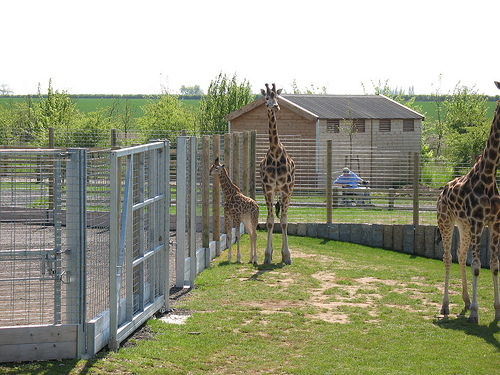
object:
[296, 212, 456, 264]
wall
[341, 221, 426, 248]
stone wall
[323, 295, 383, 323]
dirt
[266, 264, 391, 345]
ground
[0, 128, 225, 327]
area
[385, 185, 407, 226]
ground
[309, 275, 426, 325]
ground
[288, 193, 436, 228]
grass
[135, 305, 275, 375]
grass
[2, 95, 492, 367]
field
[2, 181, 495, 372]
ground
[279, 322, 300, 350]
part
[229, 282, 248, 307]
ground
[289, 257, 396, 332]
ground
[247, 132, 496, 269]
fence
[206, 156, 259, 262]
baby giraffe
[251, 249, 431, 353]
grass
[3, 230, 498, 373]
ground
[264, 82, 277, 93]
horns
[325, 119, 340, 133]
windows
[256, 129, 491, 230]
vence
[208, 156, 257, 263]
baby giraffee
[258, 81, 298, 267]
adult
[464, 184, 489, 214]
brown spots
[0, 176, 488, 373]
dirt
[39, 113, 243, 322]
fence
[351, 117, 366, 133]
windows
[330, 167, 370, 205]
person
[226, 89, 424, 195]
building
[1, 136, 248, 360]
fence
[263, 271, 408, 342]
ground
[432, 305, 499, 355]
shadow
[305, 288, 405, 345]
grass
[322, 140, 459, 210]
fence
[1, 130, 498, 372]
enclosure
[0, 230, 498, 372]
grassy area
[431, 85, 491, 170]
trees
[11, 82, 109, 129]
leaves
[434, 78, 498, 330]
giraffe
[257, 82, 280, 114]
head